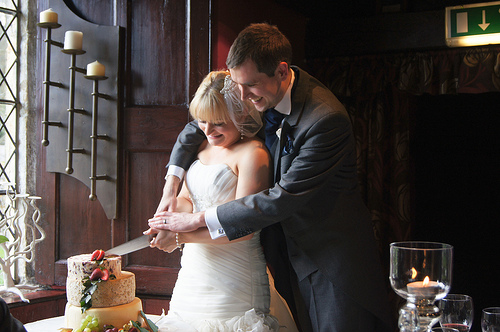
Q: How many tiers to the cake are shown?
A: 3.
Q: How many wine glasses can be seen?
A: 2.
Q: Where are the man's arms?
A: Around the woman's body.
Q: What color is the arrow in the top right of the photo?
A: White.